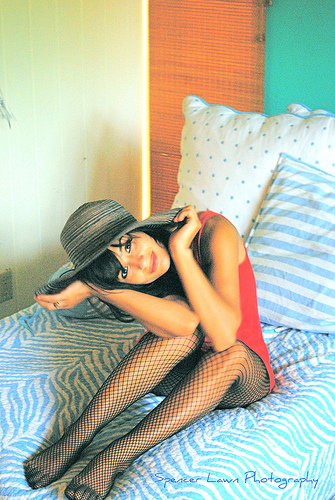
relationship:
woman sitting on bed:
[23, 207, 284, 498] [0, 260, 325, 494]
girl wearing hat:
[22, 198, 276, 499] [32, 193, 188, 294]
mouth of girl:
[140, 233, 167, 297] [5, 185, 305, 489]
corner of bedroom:
[114, 2, 176, 227] [1, 1, 332, 496]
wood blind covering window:
[219, 0, 265, 5] [148, 0, 263, 215]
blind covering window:
[149, 0, 264, 219] [148, 0, 263, 215]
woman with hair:
[84, 225, 174, 291] [72, 229, 196, 324]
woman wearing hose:
[23, 207, 284, 498] [160, 367, 207, 428]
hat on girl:
[27, 186, 208, 309] [22, 198, 276, 499]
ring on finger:
[52, 300, 63, 312] [33, 295, 66, 310]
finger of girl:
[33, 295, 66, 310] [22, 198, 276, 499]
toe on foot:
[65, 480, 77, 498] [63, 450, 127, 498]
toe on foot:
[73, 484, 83, 498] [63, 450, 127, 498]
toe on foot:
[81, 488, 90, 499] [63, 450, 127, 498]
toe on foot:
[87, 491, 95, 498] [63, 450, 127, 498]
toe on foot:
[96, 495, 102, 498] [63, 450, 127, 498]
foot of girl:
[63, 450, 127, 498] [22, 198, 276, 499]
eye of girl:
[117, 264, 130, 278] [22, 198, 276, 499]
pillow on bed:
[245, 153, 334, 337] [113, 400, 334, 498]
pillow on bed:
[174, 92, 261, 238] [113, 400, 334, 498]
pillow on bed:
[287, 100, 320, 114] [113, 400, 334, 498]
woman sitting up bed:
[23, 207, 284, 498] [0, 185, 333, 498]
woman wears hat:
[23, 207, 284, 498] [32, 193, 188, 294]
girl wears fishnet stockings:
[22, 198, 276, 499] [21, 316, 271, 498]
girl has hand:
[35, 213, 246, 318] [24, 273, 142, 335]